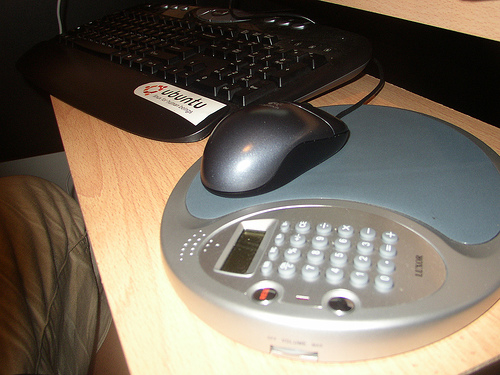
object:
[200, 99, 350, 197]
mouse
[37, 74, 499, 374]
table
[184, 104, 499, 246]
mouse pad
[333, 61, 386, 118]
cable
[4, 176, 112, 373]
shorts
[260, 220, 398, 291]
keypad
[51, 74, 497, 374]
keyboard desk shelf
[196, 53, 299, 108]
numeric key pad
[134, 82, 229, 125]
system sticker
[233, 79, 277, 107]
black keys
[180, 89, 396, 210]
mouse on desk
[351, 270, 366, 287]
buttons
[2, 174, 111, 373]
leg of a person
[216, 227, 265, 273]
digital screen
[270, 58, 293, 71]
buttons on a keyboar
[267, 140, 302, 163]
black and silver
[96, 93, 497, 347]
pad on a desk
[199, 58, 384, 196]
mouse with a cord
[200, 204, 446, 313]
calculator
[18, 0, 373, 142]
computer keyboard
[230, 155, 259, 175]
mouse is very shiny